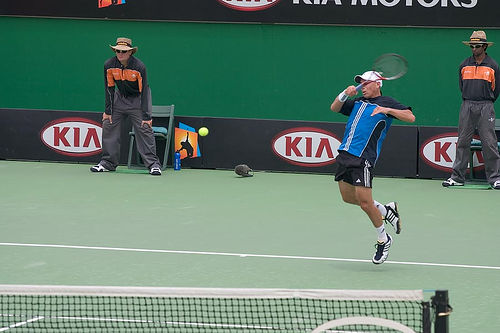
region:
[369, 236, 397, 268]
left foot of a person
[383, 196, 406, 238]
right foot of a person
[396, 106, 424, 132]
left elbow of a person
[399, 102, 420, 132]
left elbow of an athlete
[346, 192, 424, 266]
two feet on tennis court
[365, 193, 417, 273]
pair of feet on tennis court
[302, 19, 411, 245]
person swinging tennis racquet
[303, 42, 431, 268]
male person swinging tennis racquet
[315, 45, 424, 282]
player swinging tennis racquet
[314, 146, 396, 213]
person wearing black shorts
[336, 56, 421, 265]
man playing tennis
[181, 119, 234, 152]
yellow-green tennis ball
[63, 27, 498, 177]
two men standing in the background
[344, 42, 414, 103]
aluminum tennis racquet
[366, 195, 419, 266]
black and white tennis shoes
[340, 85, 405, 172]
dark grey and blue shirt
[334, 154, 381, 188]
black and white shorts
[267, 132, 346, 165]
Kia company logo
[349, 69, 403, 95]
man wearing white baseball cap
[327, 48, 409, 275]
man with both feet off the ground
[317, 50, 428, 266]
The male tennis player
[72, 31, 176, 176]
The man leaning on his knees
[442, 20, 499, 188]
The man standing up straight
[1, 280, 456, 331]
The tennis net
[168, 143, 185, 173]
The blue water bottle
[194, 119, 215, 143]
The tennis ball in the air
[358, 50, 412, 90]
The racket being held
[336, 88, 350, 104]
The player's wrist band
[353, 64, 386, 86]
The white baseball cap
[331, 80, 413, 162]
the man is wearing a blue shirt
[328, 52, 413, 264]
the man is jumping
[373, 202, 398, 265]
the man is wearing sneakers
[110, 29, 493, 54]
the men are wearing cowboy hats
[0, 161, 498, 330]
the tennis court is green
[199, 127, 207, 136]
the ball is in the air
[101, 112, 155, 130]
the man has hands on knees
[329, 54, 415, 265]
Man wearing blue shirt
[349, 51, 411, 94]
Tennis racket in man's hand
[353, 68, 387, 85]
White cap on man's head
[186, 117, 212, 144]
Tennis ball in air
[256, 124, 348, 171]
Kia logo on wall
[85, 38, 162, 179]
Man with hands on knees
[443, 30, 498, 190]
Man standing with hand's behind back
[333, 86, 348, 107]
White band on man's arm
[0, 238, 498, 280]
White line on ground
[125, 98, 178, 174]
Green chair behind man